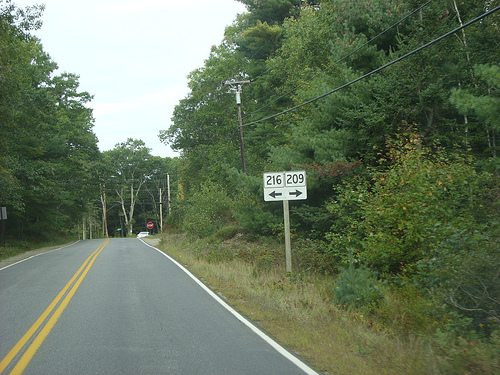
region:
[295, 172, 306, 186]
The number is black.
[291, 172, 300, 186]
The number is black.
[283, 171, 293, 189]
The number is black.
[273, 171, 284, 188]
The number is black.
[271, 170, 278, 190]
The number is black.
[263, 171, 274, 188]
The number is black.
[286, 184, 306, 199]
The arrow is black.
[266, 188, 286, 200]
The arrow is black.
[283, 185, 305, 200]
The arrow is pointing right.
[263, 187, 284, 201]
The arrow is pointing left.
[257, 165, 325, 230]
a black and white sign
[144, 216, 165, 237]
a red and white stop sign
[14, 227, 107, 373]
two yellow lines on road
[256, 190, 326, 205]
two black arrows on signs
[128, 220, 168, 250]
a white car on the road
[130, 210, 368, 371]
a white line on the road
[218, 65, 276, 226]
a pole with wires attached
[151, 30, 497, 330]
a long row of trees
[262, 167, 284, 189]
number 216 on sign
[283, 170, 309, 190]
number 209 on sign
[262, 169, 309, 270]
sign is by side of road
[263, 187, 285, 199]
arrow points left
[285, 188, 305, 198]
arrow points right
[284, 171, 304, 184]
route 209 is to the right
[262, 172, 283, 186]
route 216 is to the left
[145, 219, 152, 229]
stop sign is in the shape of an octagon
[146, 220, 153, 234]
stop sign is in the distance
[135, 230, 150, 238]
car is in the distance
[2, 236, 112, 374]
double line indicates that drivers may not pass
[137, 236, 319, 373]
white line indicates the side of the road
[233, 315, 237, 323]
edge of a road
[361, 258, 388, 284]
part of a bush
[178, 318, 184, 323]
side of a road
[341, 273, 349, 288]
part of a grass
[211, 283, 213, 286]
edge of a road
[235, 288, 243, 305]
part of a bush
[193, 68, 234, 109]
trees near a road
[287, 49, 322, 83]
trees near a road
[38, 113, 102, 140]
trees near a road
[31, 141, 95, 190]
trees near a road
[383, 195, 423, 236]
trees near a road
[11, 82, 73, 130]
trees near a road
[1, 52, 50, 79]
trees near a road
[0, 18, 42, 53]
trees near a road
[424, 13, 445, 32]
trees near a road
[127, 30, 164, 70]
a clear blue sky